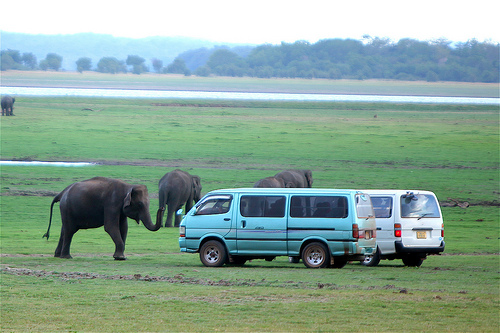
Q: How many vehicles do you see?
A: Two.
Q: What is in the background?
A: Trees.